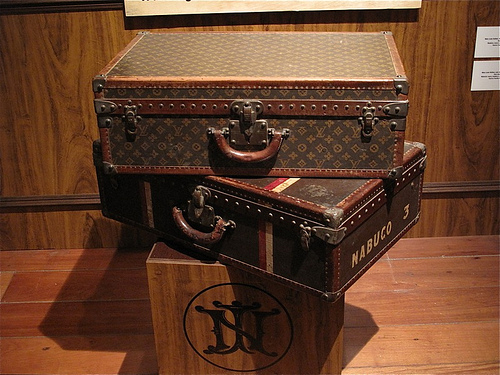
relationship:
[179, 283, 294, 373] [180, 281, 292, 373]
black logo with a circular rim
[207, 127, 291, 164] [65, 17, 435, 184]
handle attached to box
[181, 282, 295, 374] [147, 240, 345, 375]
writing on square box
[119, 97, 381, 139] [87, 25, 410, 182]
latches on box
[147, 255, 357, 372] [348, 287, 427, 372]
square box on floor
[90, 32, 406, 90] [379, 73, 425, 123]
frames attached to corner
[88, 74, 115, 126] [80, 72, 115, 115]
frames attached to corner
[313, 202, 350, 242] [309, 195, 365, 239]
frames attached to corner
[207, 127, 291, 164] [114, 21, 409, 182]
handle attached to suit case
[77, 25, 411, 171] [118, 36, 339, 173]
design on suit case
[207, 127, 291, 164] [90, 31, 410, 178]
handle on box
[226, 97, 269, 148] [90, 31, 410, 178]
lock on box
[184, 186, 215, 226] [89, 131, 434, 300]
lock on suitcase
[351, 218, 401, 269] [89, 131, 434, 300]
letters on suitcase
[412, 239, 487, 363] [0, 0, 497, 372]
brown floor in room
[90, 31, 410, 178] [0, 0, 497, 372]
box in room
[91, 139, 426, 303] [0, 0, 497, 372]
luggage in room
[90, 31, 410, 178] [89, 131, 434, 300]
box sitting on suitcase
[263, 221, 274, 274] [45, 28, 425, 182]
stripes on suitcase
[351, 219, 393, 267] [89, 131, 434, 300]
nabuco on suitcase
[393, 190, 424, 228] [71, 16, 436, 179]
3 on suitcase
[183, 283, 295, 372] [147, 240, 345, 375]
black logo on square box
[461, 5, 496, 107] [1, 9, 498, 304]
cards on wall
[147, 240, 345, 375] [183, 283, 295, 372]
square box with black logo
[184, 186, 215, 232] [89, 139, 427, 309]
lock on suitcase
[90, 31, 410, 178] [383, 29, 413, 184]
box with trim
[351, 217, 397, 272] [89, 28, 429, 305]
nabuco on luggage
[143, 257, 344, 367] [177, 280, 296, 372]
block with engraving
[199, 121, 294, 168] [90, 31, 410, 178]
handle on box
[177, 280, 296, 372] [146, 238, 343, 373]
engraving on block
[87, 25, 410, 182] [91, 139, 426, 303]
box on top of luggage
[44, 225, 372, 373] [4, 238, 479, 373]
shadow on floor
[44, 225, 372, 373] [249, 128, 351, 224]
shadow of suitcase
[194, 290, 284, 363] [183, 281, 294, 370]
letters in circular rim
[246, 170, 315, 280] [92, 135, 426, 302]
stripes on luggage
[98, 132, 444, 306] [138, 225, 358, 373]
luggage on block